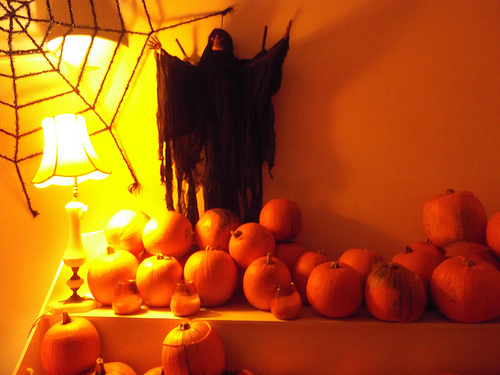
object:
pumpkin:
[101, 203, 156, 255]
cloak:
[143, 18, 293, 226]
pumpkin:
[137, 200, 200, 260]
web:
[1, 1, 239, 219]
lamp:
[26, 104, 114, 312]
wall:
[1, 0, 499, 374]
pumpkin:
[154, 308, 228, 375]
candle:
[106, 273, 146, 317]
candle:
[165, 273, 205, 319]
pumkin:
[363, 256, 431, 326]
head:
[200, 21, 238, 57]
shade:
[25, 97, 115, 194]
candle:
[269, 272, 309, 322]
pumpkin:
[28, 307, 111, 374]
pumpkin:
[81, 242, 140, 310]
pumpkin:
[258, 190, 305, 246]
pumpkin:
[223, 216, 282, 275]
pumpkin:
[131, 248, 188, 311]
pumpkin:
[178, 237, 246, 309]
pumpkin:
[236, 243, 293, 313]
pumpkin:
[299, 248, 367, 322]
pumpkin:
[425, 244, 499, 324]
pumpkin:
[337, 237, 384, 285]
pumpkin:
[290, 238, 330, 301]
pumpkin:
[380, 240, 446, 283]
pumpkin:
[419, 172, 492, 251]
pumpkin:
[188, 200, 243, 255]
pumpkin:
[270, 238, 306, 271]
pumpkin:
[481, 204, 499, 258]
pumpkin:
[88, 349, 145, 375]